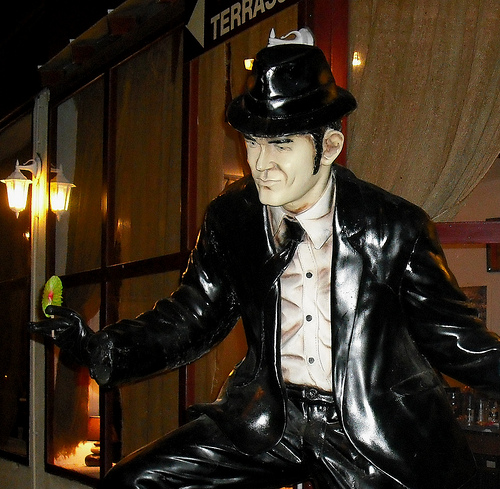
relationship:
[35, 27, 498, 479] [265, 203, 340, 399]
statue wearing shirt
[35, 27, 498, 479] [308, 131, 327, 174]
statue has hair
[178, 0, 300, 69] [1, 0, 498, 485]
sign on top of building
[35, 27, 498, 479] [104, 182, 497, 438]
statue wearing jacket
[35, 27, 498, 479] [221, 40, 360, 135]
statue wearing hat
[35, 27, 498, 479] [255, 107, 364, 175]
statue with hair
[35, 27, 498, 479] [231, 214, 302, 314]
statue with tie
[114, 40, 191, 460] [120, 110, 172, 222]
curtain in window